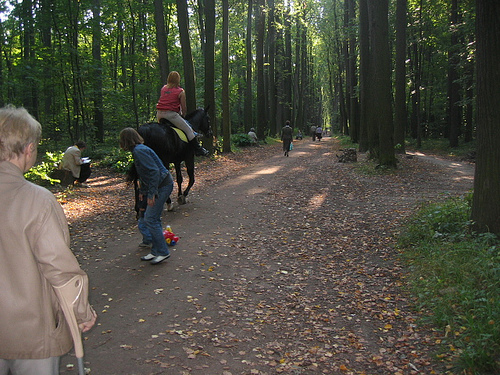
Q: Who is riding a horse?
A: A woman.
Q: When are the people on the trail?
A: During daylight hours.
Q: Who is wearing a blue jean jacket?
A: A woman.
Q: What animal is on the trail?
A: Horse.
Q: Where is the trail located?
A: In a wooded area.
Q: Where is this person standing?
A: Behind horse.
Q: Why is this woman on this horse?
A: Riding it.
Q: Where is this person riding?
A: Through the path.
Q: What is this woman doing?
A: Riding the horse.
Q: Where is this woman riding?
A: Through the path.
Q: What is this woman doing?
A: Riding the horse.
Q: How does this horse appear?
A: Black in color.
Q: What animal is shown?
A: A horse.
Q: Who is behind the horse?
A: A person.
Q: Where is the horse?
A: On a trail.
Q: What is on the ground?
A: Dead leaves.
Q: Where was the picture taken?
A: A wooded area.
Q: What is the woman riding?
A: A horse.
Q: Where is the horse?
A: On the path.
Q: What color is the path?
A: Brown.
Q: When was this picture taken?
A: Daytime.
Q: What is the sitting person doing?
A: Reading.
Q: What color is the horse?
A: Black.